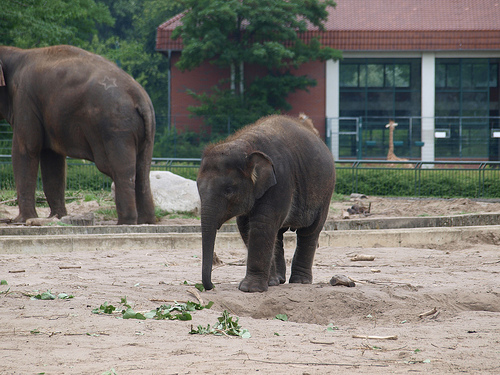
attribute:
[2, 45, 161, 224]
elephant — large, larger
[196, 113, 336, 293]
elephant — a calf, a baby, large, small, indian, walking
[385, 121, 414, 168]
giraffe — in background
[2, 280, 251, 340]
leaves — green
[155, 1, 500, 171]
building — red, big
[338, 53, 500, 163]
windows — glass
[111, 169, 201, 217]
boulder — big, white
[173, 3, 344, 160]
tree — large, growing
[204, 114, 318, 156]
hair — wiry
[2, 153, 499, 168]
bar — metal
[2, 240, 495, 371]
ground — brown